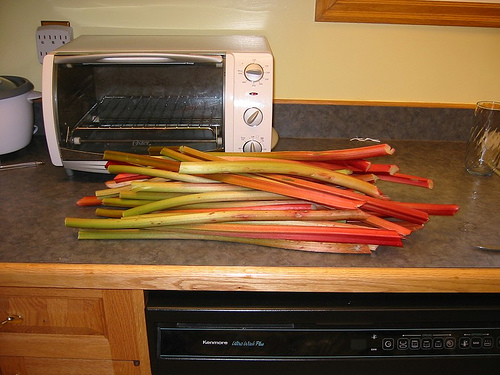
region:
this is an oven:
[38, 35, 273, 129]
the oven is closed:
[53, 40, 268, 144]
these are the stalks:
[169, 136, 316, 256]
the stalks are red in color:
[317, 143, 389, 255]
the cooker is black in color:
[238, 297, 452, 363]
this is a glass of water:
[460, 98, 495, 178]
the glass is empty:
[462, 100, 497, 170]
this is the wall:
[325, 33, 402, 100]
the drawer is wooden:
[30, 275, 110, 370]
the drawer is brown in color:
[35, 295, 106, 350]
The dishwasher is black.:
[152, 305, 498, 373]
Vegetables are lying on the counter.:
[2, 98, 499, 260]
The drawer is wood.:
[1, 286, 138, 360]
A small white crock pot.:
[0, 68, 37, 161]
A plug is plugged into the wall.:
[28, 23, 75, 70]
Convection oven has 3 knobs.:
[32, 31, 289, 183]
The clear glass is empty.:
[459, 97, 496, 182]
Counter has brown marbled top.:
[2, 106, 497, 266]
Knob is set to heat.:
[234, 56, 275, 90]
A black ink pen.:
[0, 153, 43, 175]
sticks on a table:
[40, 48, 497, 287]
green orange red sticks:
[89, 98, 496, 335]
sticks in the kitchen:
[65, 72, 481, 300]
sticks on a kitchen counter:
[21, 47, 499, 349]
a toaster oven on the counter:
[32, 20, 407, 235]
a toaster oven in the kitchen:
[21, 15, 385, 211]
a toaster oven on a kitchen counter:
[29, 11, 339, 211]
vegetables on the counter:
[48, 86, 497, 298]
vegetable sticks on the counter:
[77, 86, 487, 272]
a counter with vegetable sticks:
[60, 57, 462, 237]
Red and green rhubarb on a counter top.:
[64, 141, 458, 254]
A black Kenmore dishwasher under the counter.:
[145, 290, 499, 373]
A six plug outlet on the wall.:
[34, 23, 75, 64]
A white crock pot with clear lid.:
[0, 71, 41, 158]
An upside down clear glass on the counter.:
[466, 99, 499, 174]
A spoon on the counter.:
[467, 239, 499, 251]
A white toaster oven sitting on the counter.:
[41, 27, 273, 170]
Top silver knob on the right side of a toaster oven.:
[244, 63, 265, 82]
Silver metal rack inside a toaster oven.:
[68, 93, 225, 142]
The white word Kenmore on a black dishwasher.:
[201, 339, 228, 346]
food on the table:
[62, 127, 444, 250]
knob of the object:
[239, 56, 272, 86]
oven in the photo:
[75, 53, 226, 143]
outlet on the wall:
[16, 15, 81, 69]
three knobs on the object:
[232, 58, 274, 154]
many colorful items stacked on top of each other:
[106, 116, 424, 262]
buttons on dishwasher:
[354, 329, 464, 369]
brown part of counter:
[0, 288, 105, 355]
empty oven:
[72, 65, 222, 143]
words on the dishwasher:
[188, 335, 290, 355]